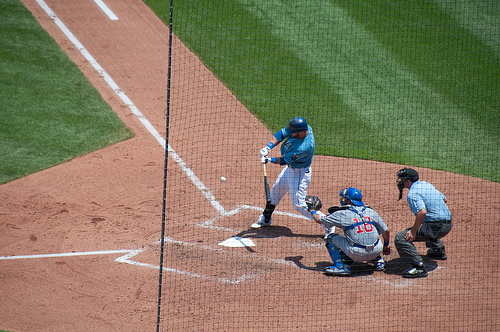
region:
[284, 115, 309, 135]
blue helmet on the batter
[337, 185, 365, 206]
blue helmet on the catcher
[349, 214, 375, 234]
red numbers on the gray shirt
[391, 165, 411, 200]
black face mask on the umpire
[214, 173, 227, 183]
white baseball in the air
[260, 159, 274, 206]
black and tan baseball bat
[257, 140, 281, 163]
white and blue batting gloves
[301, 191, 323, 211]
black glove on the catcher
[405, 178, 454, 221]
blue shirt on the umpire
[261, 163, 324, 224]
white pants on the batter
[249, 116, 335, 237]
a baseball player at bat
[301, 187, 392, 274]
a baseball catcher crouching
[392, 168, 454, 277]
a baseball umpire crouching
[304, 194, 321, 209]
a black leather catcher's mitt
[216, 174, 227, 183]
a white baseball in flight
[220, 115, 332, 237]
a baseball player swinging at ball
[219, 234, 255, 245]
a white home plate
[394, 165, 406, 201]
a black protective face mask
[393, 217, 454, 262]
a pair of grey pants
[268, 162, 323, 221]
a pair of white pants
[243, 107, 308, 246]
batter is swinging the bat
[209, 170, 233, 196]
baseball is in the air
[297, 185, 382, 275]
catcher is waiting for the ball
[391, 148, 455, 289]
umpire is crouched behind the catcher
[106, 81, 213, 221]
white chalk line down the baseline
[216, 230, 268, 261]
home plate in front of the catcher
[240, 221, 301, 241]
shadow on the ground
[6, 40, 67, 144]
green grass of the infield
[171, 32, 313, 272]
net behind home plate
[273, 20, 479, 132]
lines in the grass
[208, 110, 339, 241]
a man swinging a bat at a ball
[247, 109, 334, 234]
a man swinging a bat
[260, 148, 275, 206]
a man holding a baseball bat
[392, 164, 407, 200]
a man with a catcher's mask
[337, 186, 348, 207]
a man with a catcher's mask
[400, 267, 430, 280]
a man with black shoes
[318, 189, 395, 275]
a baseball uniform with the number 18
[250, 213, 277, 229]
a man with white shoes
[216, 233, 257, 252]
a diamond on a baseball base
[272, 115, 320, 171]
a man in a blue baseball uniform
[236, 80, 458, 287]
the men play baseball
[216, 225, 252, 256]
home plate rests under the man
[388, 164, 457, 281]
the umpire sits behind the catcher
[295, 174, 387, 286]
the catcher sits behind the batter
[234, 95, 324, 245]
the man is up at bat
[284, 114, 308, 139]
the player wears a helmet